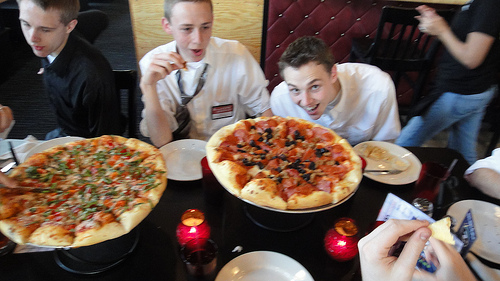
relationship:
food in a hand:
[429, 212, 457, 246] [353, 219, 474, 280]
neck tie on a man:
[170, 60, 210, 135] [132, 0, 278, 151]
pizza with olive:
[201, 112, 361, 207] [242, 119, 339, 184]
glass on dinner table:
[413, 140, 463, 215] [1, 132, 498, 277]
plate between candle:
[347, 138, 420, 187] [172, 205, 210, 252]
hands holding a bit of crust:
[351, 196, 479, 279] [422, 212, 462, 242]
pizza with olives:
[201, 112, 361, 207] [281, 155, 303, 169]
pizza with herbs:
[200, 93, 372, 239] [30, 155, 144, 233]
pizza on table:
[2, 127, 169, 261] [1, 132, 498, 277]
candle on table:
[174, 207, 213, 252] [1, 132, 498, 277]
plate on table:
[351, 132, 425, 179] [0, 142, 478, 274]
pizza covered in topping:
[201, 112, 361, 207] [245, 131, 264, 147]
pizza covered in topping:
[201, 112, 361, 207] [291, 155, 311, 168]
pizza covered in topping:
[201, 112, 361, 207] [276, 164, 306, 192]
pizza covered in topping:
[201, 112, 361, 207] [230, 129, 265, 155]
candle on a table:
[174, 207, 213, 252] [31, 145, 451, 266]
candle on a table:
[322, 215, 362, 257] [31, 145, 451, 266]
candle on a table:
[174, 207, 213, 252] [62, 145, 382, 271]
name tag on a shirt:
[208, 102, 235, 120] [126, 36, 276, 139]